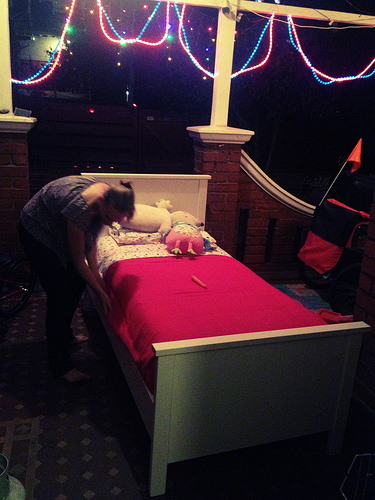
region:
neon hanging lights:
[250, 7, 372, 98]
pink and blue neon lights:
[259, 11, 373, 104]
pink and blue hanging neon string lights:
[283, 13, 364, 99]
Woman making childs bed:
[10, 162, 168, 403]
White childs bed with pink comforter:
[64, 161, 369, 425]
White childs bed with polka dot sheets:
[68, 152, 363, 409]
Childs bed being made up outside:
[8, 4, 373, 408]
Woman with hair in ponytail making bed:
[17, 149, 190, 412]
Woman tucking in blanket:
[8, 144, 151, 394]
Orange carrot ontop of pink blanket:
[151, 250, 238, 327]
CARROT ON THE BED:
[189, 269, 212, 295]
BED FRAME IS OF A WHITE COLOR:
[58, 168, 359, 492]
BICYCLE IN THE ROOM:
[4, 264, 34, 316]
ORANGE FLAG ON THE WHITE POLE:
[323, 129, 362, 205]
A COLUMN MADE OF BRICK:
[201, 139, 243, 244]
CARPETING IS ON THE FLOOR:
[2, 137, 171, 490]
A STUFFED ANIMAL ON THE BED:
[160, 199, 202, 268]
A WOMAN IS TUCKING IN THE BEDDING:
[21, 141, 148, 382]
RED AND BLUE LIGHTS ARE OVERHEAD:
[12, 1, 372, 80]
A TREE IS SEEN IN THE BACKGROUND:
[201, 11, 288, 171]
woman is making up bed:
[16, 158, 164, 358]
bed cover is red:
[101, 247, 342, 409]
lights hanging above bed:
[3, 2, 353, 113]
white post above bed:
[3, 2, 372, 130]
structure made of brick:
[4, 127, 364, 304]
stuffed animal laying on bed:
[161, 202, 221, 269]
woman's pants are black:
[26, 221, 108, 381]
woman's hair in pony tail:
[105, 176, 138, 216]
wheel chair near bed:
[307, 183, 370, 322]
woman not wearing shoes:
[47, 313, 133, 415]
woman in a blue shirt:
[20, 173, 137, 331]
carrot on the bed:
[182, 270, 209, 302]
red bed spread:
[95, 248, 350, 366]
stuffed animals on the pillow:
[115, 185, 220, 263]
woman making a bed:
[18, 162, 138, 342]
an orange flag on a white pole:
[324, 138, 369, 189]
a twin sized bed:
[58, 161, 363, 477]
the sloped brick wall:
[199, 136, 352, 292]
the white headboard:
[78, 165, 205, 230]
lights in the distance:
[68, 156, 117, 173]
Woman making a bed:
[33, 171, 117, 363]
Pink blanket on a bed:
[111, 248, 303, 328]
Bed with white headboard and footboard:
[95, 170, 355, 463]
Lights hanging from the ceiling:
[58, 3, 202, 82]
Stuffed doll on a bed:
[171, 208, 206, 271]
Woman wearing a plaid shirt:
[29, 180, 100, 257]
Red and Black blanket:
[301, 186, 362, 281]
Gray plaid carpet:
[22, 375, 111, 473]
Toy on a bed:
[185, 266, 212, 294]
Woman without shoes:
[44, 357, 90, 385]